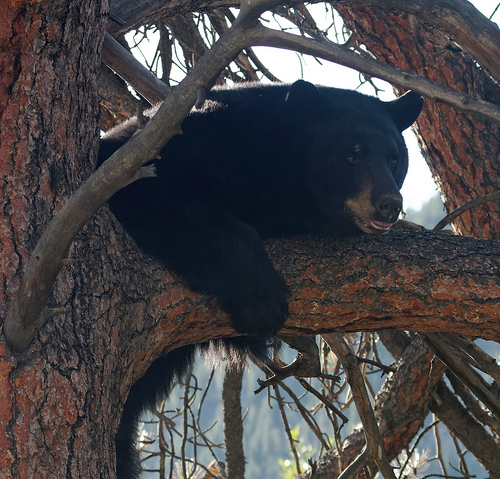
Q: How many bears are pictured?
A: One.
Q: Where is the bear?
A: In the tree.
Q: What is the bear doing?
A: Climbing a tree.